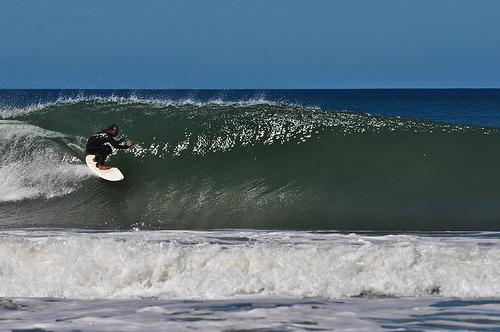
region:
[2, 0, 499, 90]
The sky is blue.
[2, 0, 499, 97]
The sky is clear.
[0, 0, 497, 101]
The sky is cloudless.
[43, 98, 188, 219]
The man is on a surfboard.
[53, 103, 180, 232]
The man is crouching.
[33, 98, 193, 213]
The man is barefoot.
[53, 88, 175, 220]
The man is wearing a wetsuit.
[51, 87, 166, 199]
The man's wetsuit is black.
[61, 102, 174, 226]
The surfboard is in the water.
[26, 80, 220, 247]
The surfboard is white.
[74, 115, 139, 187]
the man is crouched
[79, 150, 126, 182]
the white surfboard on sea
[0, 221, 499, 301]
the water is foamy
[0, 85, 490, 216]
water is rolling in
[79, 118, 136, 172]
man wears black clothes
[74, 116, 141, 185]
man stand on surfboard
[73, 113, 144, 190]
surfer goes to the right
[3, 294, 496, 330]
the water is foamy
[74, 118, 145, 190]
the man is barefoot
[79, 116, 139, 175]
man has black hair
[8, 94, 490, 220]
one surfer riding ocean wave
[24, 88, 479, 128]
one dark ocean wave breaking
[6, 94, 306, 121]
white capped ocean wave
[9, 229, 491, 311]
frothy white ocean water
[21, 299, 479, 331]
bubbly ocean water coming onto beach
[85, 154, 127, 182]
one white surfboard in ocean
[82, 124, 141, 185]
one male surfer crouched on board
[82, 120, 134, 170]
one surfer wearing wetsuit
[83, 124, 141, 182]
one male surfer with arms outstretched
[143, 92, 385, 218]
section of sunlit ocean waves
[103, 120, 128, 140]
head of a person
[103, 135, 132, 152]
arm of a person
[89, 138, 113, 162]
leg of a person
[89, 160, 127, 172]
feet of a person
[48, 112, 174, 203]
person on a board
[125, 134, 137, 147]
hand of a person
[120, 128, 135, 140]
hand of a person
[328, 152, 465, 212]
body of a water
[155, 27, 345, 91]
a clear blue sky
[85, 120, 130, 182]
person standing on white surfboard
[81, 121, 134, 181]
person wearing black wet suit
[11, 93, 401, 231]
tall wave of green foamy waters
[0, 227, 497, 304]
wave of green foamy waters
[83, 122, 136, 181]
people kneeling to stay balanced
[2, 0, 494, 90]
bright blue clear sky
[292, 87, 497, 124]
blue clam ocean in the distance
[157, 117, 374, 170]
sun is reflecting on green wave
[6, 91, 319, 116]
white foam on crest of wave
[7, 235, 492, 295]
lot of foam on body of water